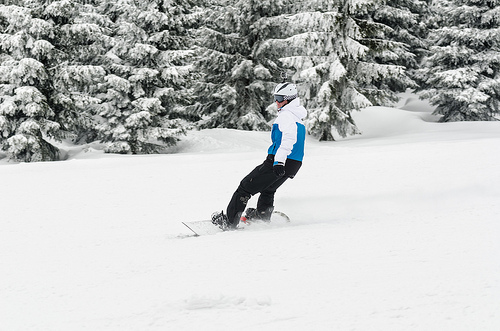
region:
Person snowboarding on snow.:
[178, 75, 312, 238]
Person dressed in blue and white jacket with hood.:
[263, 97, 313, 167]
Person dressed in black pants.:
[223, 164, 288, 225]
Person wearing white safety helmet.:
[273, 77, 301, 98]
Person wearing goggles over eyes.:
[269, 91, 299, 103]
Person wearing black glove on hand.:
[270, 160, 290, 180]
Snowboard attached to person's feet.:
[176, 208, 293, 238]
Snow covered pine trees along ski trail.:
[8, 4, 234, 159]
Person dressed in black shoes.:
[211, 208, 278, 231]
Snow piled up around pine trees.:
[348, 99, 498, 146]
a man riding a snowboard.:
[170, 64, 323, 244]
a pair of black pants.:
[223, 157, 302, 222]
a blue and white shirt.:
[266, 97, 311, 164]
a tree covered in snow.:
[245, 0, 360, 150]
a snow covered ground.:
[0, 120, 499, 327]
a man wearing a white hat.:
[264, 75, 301, 102]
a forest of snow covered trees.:
[0, 0, 497, 165]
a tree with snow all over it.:
[409, 0, 497, 122]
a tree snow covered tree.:
[90, 0, 223, 156]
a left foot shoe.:
[205, 208, 235, 233]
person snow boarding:
[187, 74, 326, 254]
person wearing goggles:
[269, 81, 296, 109]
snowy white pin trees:
[45, 14, 189, 161]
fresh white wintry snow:
[107, 276, 247, 301]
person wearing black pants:
[223, 152, 312, 232]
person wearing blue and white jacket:
[258, 107, 315, 169]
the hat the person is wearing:
[269, 75, 298, 95]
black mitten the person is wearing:
[272, 163, 290, 180]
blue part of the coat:
[297, 125, 306, 165]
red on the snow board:
[237, 212, 250, 228]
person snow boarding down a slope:
[181, 78, 308, 231]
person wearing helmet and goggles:
[269, 78, 304, 105]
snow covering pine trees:
[1, 0, 496, 158]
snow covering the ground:
[1, 106, 497, 329]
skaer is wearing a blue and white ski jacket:
[266, 98, 308, 162]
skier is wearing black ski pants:
[218, 156, 290, 220]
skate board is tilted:
[179, 208, 291, 240]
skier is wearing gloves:
[269, 162, 288, 178]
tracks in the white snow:
[137, 280, 492, 329]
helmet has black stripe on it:
[273, 80, 300, 95]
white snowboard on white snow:
[182, 208, 291, 238]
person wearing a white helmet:
[275, 78, 295, 96]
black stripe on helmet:
[277, 80, 290, 90]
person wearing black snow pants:
[226, 158, 300, 220]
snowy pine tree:
[96, 0, 197, 155]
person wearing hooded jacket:
[267, 98, 308, 168]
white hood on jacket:
[283, 96, 307, 120]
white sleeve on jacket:
[275, 115, 297, 163]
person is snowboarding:
[213, 78, 310, 222]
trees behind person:
[1, 0, 498, 159]